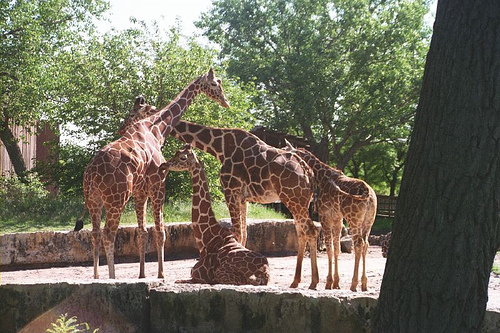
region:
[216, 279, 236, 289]
part of an edge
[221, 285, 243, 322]
poart of a wa;ll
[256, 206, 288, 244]
part of a wall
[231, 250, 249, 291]
part of a tail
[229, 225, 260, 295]
part of a bancki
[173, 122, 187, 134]
brown spot on giraffe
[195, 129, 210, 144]
brown spot on giraffe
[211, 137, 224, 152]
brown spot on giraffe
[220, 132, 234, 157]
brown spot on giraffe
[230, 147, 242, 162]
brown spot on giraffe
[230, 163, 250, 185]
brown spot on giraffe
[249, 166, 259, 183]
brown spot on giraffe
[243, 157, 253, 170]
brown spot on giraffe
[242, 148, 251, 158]
brown spot on giraffe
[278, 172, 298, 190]
brown spot on giraffe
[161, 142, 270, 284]
the giraffe is lying down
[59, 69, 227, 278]
the giraffe is standing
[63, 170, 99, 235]
the giraffe has a tail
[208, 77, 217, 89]
the giraffe has an eye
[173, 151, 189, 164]
the giraffes eye is dark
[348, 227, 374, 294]
the giraffe has hind legs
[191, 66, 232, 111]
the giraffe has a head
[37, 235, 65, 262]
the wall is tan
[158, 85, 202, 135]
the giraffe has a long neck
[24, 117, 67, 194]
the fence is tall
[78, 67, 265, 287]
this is a branch of a tree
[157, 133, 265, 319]
this is a branch of a tree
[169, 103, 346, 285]
this is a branch of a tree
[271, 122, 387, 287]
this is a branch of a tree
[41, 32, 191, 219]
this is a tree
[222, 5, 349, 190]
this is a tree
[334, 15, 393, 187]
this is a tree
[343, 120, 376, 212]
this is a tree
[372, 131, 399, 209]
this is a tree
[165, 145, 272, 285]
Giraffe laying on the ground.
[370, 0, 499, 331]
Tree trunk in the forefront.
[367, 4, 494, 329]
Brown bark on the tree.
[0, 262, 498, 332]
Stone wall behind the tree.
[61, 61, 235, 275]
Giraffe standing on the ground.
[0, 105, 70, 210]
Wood fence in the background.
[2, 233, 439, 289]
Dirt covering the ground.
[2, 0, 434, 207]
Trees in the background.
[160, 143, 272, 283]
Brown spots on the giraffe.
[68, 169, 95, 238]
black hair on the end of the tail.